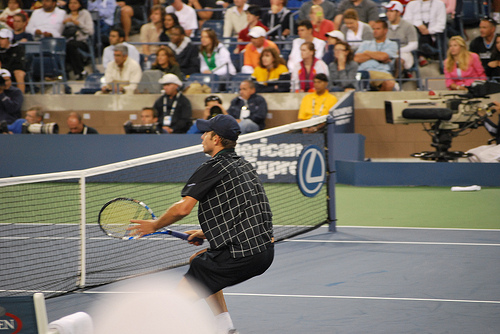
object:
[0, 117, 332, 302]
net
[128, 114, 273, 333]
man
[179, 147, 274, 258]
plaid shirt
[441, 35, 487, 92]
woman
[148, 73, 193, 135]
man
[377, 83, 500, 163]
camera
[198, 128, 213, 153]
face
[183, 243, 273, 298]
black shorts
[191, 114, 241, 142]
cap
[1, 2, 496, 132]
people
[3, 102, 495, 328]
match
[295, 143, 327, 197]
design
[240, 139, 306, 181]
print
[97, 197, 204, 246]
racket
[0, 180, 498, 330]
tennis court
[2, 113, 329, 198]
trim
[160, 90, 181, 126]
lanyard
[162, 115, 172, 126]
pass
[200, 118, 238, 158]
head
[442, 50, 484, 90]
blazer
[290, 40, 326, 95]
person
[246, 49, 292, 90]
person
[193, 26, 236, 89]
person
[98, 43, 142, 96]
person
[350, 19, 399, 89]
person